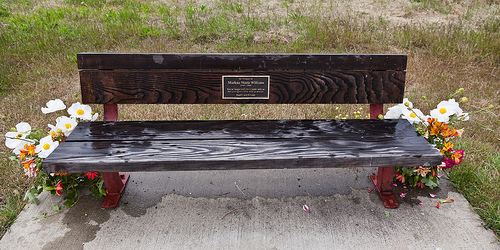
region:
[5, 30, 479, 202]
wooden bench with memorial plaque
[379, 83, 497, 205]
flower arrangement alongside bench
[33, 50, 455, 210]
outdoor bench for seating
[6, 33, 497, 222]
rainsoaked outdoor bench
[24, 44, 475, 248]
outdoor bench bolted into cement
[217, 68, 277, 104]
memorial plaque mounted back back of a park bench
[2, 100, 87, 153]
showy white flowers with yellow center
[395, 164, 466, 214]
flower blossoms falling onto cement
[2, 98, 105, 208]
floral arrangement of white, orange and pink blossoms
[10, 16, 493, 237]
a vacant wet outdoor bench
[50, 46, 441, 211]
There is a wooden bench.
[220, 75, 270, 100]
A small black sign on the back of the bench.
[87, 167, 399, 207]
The bench has red metal legs.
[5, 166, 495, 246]
The bench is on a concrete slab.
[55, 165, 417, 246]
The concrete slab under the bench is wet.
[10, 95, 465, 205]
There are flowers on both sides of the bench.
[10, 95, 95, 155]
There are yellow and white flowers next to the bench.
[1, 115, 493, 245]
The concrete slab is surrounded by grass.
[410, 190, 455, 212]
There are flower petals on the ground.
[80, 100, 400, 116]
A space below the back portion of the bench.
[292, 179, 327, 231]
part of a floor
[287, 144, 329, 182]
edge of a bench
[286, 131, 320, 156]
part of a bench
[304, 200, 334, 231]
part of a floor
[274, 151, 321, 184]
part of a bench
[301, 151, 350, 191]
edge of a bench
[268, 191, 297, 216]
part fo a floor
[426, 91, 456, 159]
part of a flower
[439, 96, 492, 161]
part of a ground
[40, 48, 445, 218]
Black bench with plaque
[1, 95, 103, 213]
Flowers on left side of bench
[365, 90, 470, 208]
Flowers on right side of bench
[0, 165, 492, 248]
Cement area for bench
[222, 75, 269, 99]
Small plaque on bench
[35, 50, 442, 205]
Dark black bench next to bushes of flowers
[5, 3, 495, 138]
Green grass nearby dark black bench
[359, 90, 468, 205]
Flower bush next to plagued bench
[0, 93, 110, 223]
Other bush of flowers nearby plaqued bench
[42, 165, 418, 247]
Wet cement area nearby bench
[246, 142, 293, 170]
part of a bench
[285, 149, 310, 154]
edge of a bench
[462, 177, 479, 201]
part of a lawn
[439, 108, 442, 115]
part of a flower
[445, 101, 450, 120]
part of a flower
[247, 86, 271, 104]
back of a seat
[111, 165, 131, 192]
bottom of a bench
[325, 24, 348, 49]
part of a field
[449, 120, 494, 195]
edge of a lawn